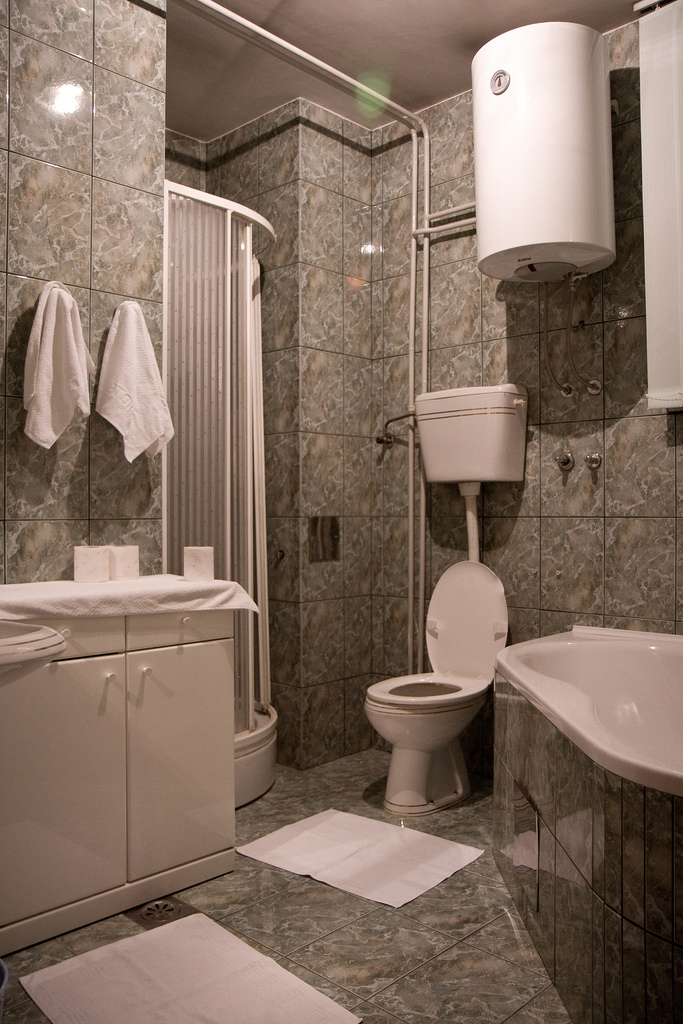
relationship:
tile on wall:
[342, 353, 375, 434] [301, 98, 371, 767]